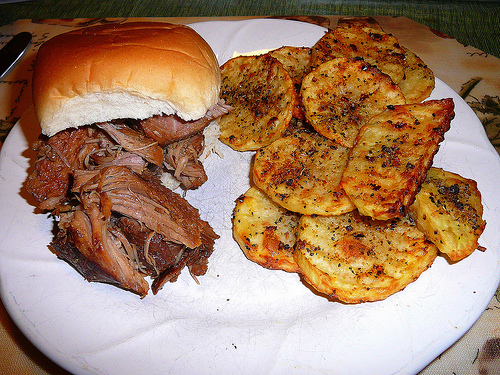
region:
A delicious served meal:
[0, 17, 499, 374]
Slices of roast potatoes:
[222, 18, 479, 310]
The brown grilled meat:
[29, 99, 226, 296]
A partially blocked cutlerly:
[0, 28, 31, 91]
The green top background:
[0, 0, 499, 57]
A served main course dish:
[0, 0, 498, 374]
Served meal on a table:
[1, 0, 498, 374]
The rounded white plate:
[0, 17, 498, 372]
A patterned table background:
[0, 20, 498, 373]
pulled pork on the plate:
[40, 135, 203, 293]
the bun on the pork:
[40, 21, 215, 116]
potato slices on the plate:
[232, 20, 462, 262]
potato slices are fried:
[235, 30, 470, 251]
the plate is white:
[0, 11, 485, 371]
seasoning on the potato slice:
[275, 145, 320, 180]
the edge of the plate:
[420, 290, 490, 361]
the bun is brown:
[31, 20, 214, 107]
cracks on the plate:
[195, 185, 241, 232]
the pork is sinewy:
[27, 145, 212, 272]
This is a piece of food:
[294, 200, 436, 325]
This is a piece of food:
[54, 199, 183, 336]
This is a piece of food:
[103, 150, 249, 277]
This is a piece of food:
[340, 79, 465, 231]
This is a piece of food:
[398, 155, 495, 263]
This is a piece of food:
[236, 174, 346, 309]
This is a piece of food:
[243, 130, 378, 219]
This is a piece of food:
[208, 37, 302, 161]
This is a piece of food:
[303, 32, 419, 161]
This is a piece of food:
[38, 17, 259, 187]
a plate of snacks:
[36, 62, 411, 371]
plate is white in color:
[212, 260, 350, 366]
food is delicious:
[48, 107, 371, 302]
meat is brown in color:
[53, 137, 200, 281]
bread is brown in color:
[56, 35, 186, 113]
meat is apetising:
[54, 149, 181, 267]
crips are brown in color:
[283, 57, 410, 249]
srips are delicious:
[278, 71, 407, 336]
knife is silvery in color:
[1, 20, 56, 67]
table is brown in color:
[438, 27, 498, 105]